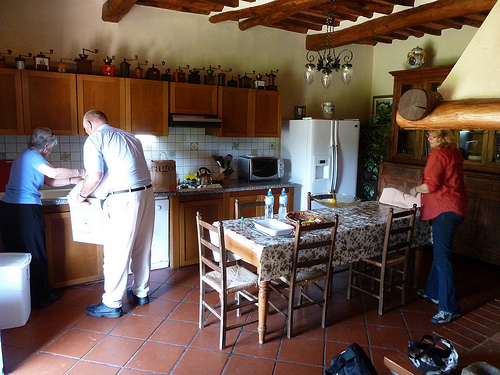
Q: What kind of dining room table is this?
A: Wooden.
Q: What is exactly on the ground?
A: Red tiles.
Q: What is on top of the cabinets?
A: A collection of old coffee grinders.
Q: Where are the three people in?
A: A kitchen.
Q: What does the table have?
A: Five wooden chairs.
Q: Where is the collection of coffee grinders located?
A: On a shelf.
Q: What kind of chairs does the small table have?
A: Wooden chairs.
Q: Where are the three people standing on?
A: Inside a kitchen.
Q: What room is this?
A: A kitchen.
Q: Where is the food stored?
A: In the refrigerator.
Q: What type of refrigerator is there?
A: A side by side refrigerator.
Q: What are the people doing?
A: Preparing a meal.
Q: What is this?
A: A kitchen.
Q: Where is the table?
A: In front of the refrigerator.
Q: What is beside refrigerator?
A: A microwave.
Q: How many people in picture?
A: Three.